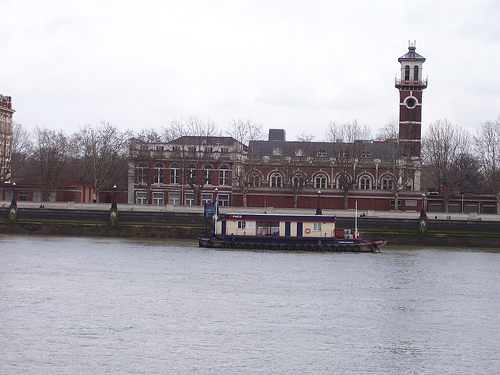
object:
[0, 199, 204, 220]
railing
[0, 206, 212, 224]
train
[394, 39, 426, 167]
clocktower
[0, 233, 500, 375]
river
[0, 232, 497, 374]
water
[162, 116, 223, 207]
tree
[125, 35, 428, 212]
building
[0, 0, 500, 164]
sky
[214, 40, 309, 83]
cloud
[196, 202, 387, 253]
boat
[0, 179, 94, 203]
building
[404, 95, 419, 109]
clock